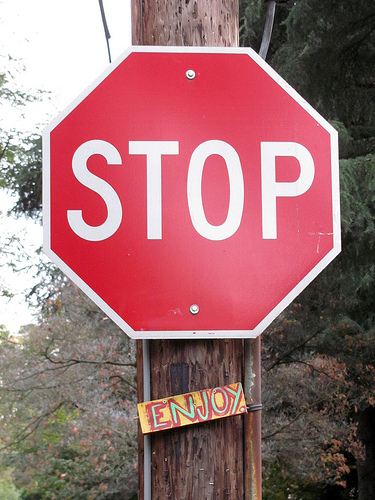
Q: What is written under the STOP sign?
A: Enjoy.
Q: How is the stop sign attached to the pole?
A: With screws.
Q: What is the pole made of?
A: Wood.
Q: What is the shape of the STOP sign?
A: Octagon.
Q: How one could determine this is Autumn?
A: The leaves are red.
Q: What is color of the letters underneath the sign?
A: Green and red.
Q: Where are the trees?
A: Behind the STOP sign.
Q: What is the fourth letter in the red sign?
A: P.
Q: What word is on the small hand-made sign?
A: Enjoy.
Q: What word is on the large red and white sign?
A: STOP.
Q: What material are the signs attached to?
A: Wood.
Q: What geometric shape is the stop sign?
A: Octagon.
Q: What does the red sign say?
A: Stop.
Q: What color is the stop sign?
A: Red.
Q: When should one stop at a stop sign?
A: When driving.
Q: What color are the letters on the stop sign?
A: White.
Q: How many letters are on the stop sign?
A: Four.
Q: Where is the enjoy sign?
A: Under stop sign.